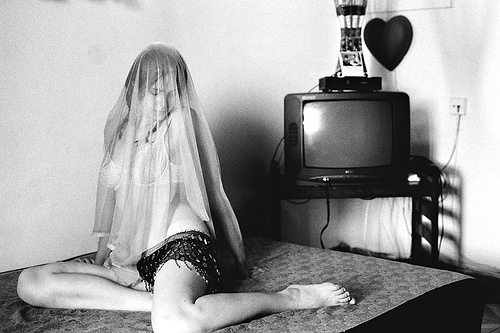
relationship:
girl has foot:
[15, 41, 357, 332] [281, 280, 356, 310]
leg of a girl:
[16, 260, 150, 310] [15, 41, 357, 332]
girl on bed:
[15, 41, 357, 332] [0, 235, 484, 330]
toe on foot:
[340, 297, 357, 306] [281, 280, 356, 310]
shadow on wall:
[425, 2, 488, 270] [273, 0, 491, 326]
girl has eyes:
[15, 41, 357, 332] [143, 88, 180, 104]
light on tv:
[298, 100, 329, 150] [284, 87, 414, 188]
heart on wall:
[360, 15, 412, 72] [302, 0, 498, 277]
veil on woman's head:
[89, 42, 254, 288] [123, 44, 190, 130]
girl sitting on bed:
[15, 41, 357, 332] [3, 223, 476, 326]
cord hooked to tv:
[316, 194, 333, 253] [275, 82, 420, 187]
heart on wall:
[351, 10, 413, 72] [273, 0, 491, 326]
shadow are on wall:
[407, 166, 465, 269] [264, 2, 496, 286]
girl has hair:
[15, 41, 357, 332] [107, 38, 186, 141]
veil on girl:
[89, 42, 254, 288] [11, 36, 356, 329]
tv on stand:
[284, 87, 414, 188] [270, 159, 443, 265]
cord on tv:
[318, 179, 333, 248] [275, 82, 420, 187]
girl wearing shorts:
[11, 36, 356, 329] [129, 232, 220, 285]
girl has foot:
[11, 36, 356, 329] [276, 273, 357, 315]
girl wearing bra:
[11, 36, 356, 329] [97, 122, 198, 187]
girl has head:
[11, 36, 356, 329] [124, 47, 185, 128]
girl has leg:
[11, 36, 356, 329] [143, 240, 354, 330]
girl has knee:
[11, 36, 356, 329] [14, 260, 61, 306]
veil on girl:
[93, 36, 227, 252] [15, 41, 357, 332]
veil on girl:
[89, 42, 254, 288] [15, 41, 357, 332]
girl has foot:
[15, 41, 357, 332] [275, 276, 358, 314]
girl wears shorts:
[15, 41, 357, 332] [137, 225, 226, 285]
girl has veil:
[15, 41, 357, 332] [103, 40, 253, 270]